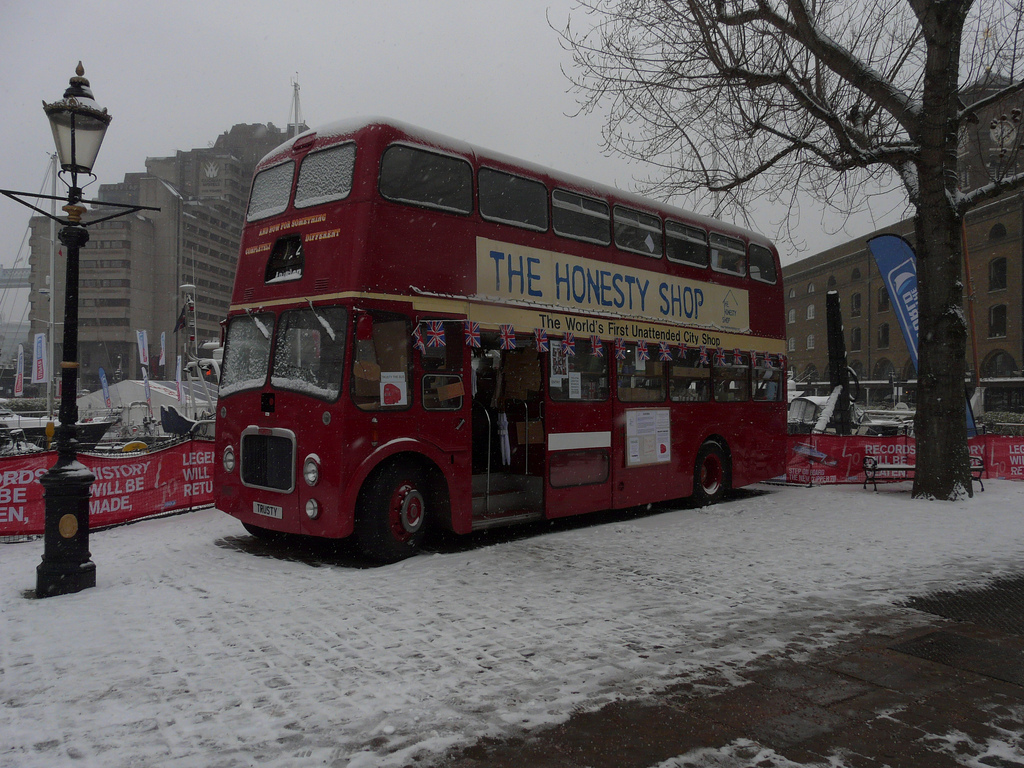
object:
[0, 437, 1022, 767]
snow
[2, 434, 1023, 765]
ground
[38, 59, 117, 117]
snow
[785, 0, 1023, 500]
background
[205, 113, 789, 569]
big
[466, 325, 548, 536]
door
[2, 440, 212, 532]
red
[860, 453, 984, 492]
bench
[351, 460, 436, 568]
big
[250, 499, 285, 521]
plate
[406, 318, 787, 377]
flag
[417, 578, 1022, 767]
cobblestone.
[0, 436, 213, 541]
fencing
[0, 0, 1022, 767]
winter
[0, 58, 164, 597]
iron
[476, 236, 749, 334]
advertisment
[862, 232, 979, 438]
sign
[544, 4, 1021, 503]
leaves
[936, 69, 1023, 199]
clocktower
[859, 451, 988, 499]
metal